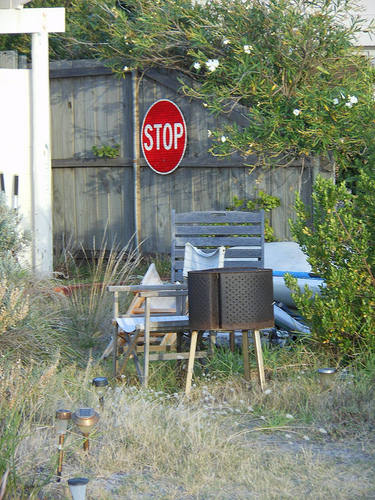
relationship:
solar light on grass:
[77, 407, 96, 462] [100, 430, 242, 478]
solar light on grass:
[55, 409, 71, 484] [100, 430, 242, 478]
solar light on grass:
[94, 377, 109, 407] [100, 430, 242, 478]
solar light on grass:
[72, 476, 92, 499] [100, 430, 242, 478]